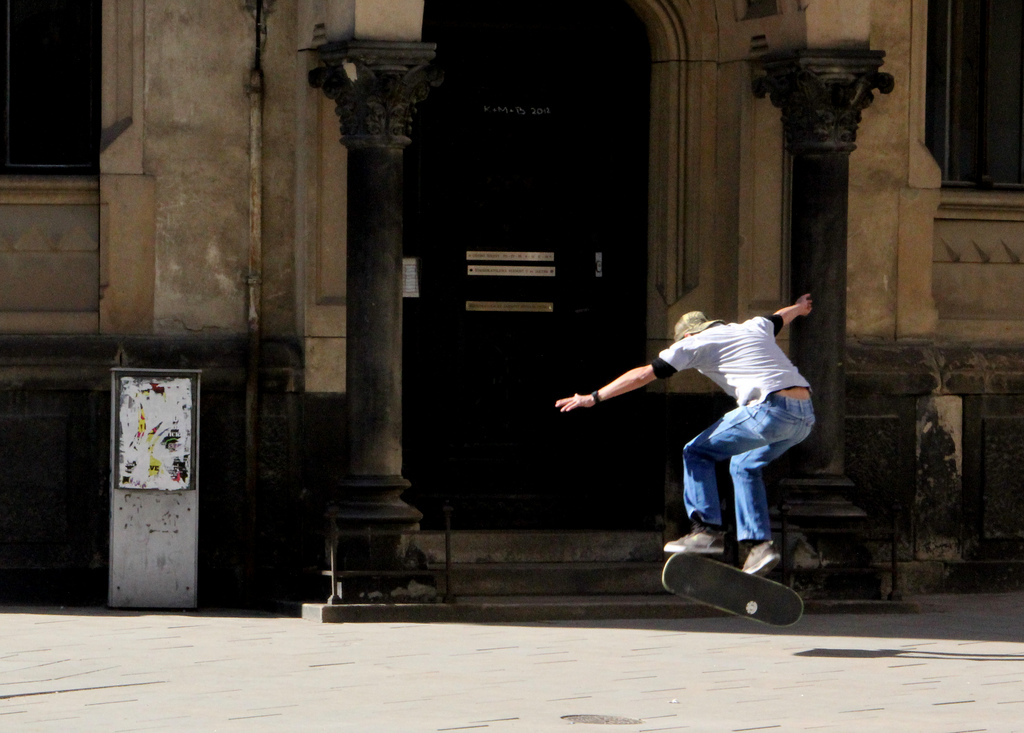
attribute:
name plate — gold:
[466, 250, 552, 266]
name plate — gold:
[466, 266, 553, 277]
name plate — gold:
[464, 298, 551, 315]